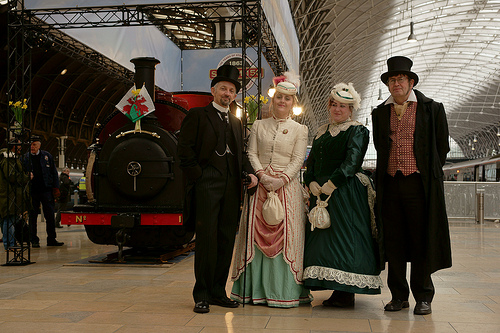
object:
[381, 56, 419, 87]
hat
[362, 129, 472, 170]
window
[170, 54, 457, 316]
group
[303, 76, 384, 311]
woman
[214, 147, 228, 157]
chain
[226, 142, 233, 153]
watch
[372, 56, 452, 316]
man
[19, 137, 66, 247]
man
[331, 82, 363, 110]
hat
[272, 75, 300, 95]
hat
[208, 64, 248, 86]
hat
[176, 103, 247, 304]
suit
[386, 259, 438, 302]
legs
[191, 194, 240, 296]
legs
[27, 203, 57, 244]
legs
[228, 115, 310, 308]
dress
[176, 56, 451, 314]
man wearing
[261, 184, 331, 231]
purses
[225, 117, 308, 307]
white dress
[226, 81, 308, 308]
girl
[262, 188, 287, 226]
purse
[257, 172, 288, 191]
hand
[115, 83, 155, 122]
decoration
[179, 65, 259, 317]
man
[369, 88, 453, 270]
coat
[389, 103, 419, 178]
vest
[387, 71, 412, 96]
head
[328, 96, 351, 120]
head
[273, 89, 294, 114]
head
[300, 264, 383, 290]
details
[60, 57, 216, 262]
engine car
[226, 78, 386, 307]
women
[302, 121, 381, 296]
dress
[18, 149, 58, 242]
suit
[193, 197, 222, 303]
leg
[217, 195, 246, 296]
leg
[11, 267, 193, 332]
ground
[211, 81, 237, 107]
head